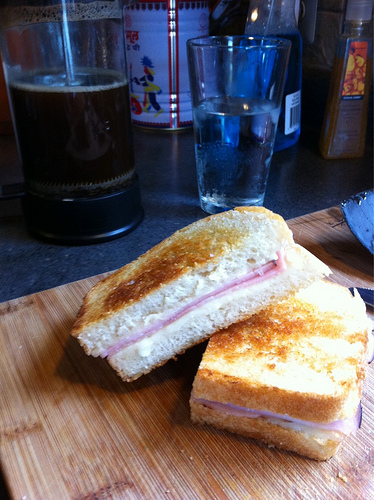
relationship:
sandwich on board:
[190, 280, 372, 461] [0, 202, 374, 499]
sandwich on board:
[70, 202, 305, 386] [0, 202, 374, 499]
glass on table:
[184, 27, 293, 215] [4, 123, 372, 263]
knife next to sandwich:
[341, 279, 373, 309] [66, 203, 370, 460]